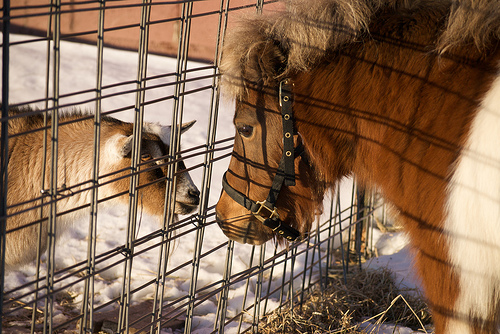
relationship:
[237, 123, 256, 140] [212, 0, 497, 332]
eye belongs to animal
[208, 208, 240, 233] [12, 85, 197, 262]
nostril belongs to animal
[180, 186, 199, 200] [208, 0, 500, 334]
nostril belongs to pony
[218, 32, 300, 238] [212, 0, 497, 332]
harness worn by animal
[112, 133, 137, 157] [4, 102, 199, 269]
ear belongs to animal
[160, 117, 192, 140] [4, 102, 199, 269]
ear belongs to animal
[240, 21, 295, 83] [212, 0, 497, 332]
ear belongs to animal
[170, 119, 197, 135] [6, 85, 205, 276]
ear belongs to animal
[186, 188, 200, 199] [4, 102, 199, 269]
nose belongs to animal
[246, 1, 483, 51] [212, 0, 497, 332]
mane belongs to animal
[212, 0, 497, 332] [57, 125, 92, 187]
animal looks at animal